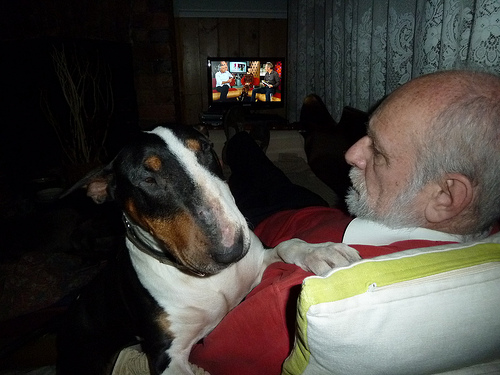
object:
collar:
[120, 212, 205, 277]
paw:
[295, 242, 363, 277]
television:
[207, 57, 287, 109]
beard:
[344, 167, 428, 231]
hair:
[415, 71, 499, 244]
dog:
[57, 122, 360, 374]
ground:
[416, 152, 448, 194]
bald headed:
[414, 70, 500, 101]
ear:
[425, 174, 473, 224]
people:
[215, 65, 234, 102]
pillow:
[282, 235, 500, 375]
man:
[175, 61, 498, 333]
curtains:
[287, 0, 500, 124]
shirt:
[188, 207, 500, 374]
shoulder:
[286, 234, 447, 301]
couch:
[280, 235, 499, 374]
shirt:
[215, 71, 234, 89]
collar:
[341, 217, 492, 246]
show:
[211, 61, 283, 104]